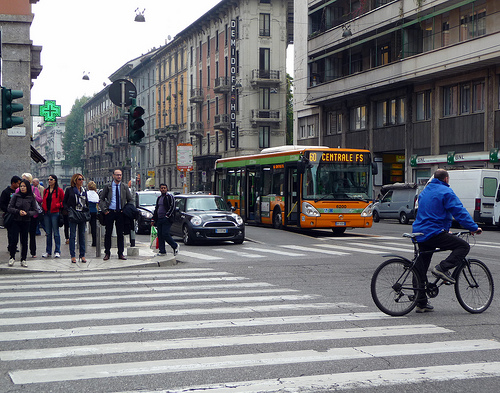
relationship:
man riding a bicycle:
[410, 166, 482, 313] [370, 228, 493, 317]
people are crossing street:
[2, 167, 174, 268] [0, 221, 498, 392]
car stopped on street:
[167, 192, 246, 246] [0, 221, 498, 392]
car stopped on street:
[131, 190, 159, 233] [0, 221, 498, 392]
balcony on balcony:
[306, 1, 496, 109] [306, 1, 496, 109]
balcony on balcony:
[250, 49, 281, 89] [306, 1, 496, 109]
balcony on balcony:
[251, 88, 282, 125] [306, 1, 496, 109]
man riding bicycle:
[410, 166, 482, 313] [370, 228, 493, 317]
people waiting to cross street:
[2, 167, 174, 268] [0, 221, 498, 392]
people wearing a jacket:
[2, 167, 174, 268] [40, 186, 65, 215]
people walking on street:
[2, 167, 174, 268] [0, 221, 498, 392]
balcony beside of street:
[306, 1, 496, 109] [0, 221, 498, 392]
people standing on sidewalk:
[2, 167, 174, 268] [2, 222, 179, 274]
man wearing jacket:
[410, 166, 482, 313] [412, 179, 479, 244]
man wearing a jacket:
[410, 166, 482, 313] [412, 179, 479, 244]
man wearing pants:
[410, 166, 482, 313] [415, 231, 469, 304]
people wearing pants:
[2, 167, 174, 268] [155, 221, 176, 250]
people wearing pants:
[2, 167, 174, 268] [105, 209, 126, 253]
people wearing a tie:
[2, 167, 174, 268] [114, 184, 121, 210]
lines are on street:
[1, 234, 498, 392] [0, 221, 498, 392]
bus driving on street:
[213, 143, 373, 233] [0, 221, 498, 392]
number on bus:
[307, 149, 319, 164] [213, 143, 373, 233]